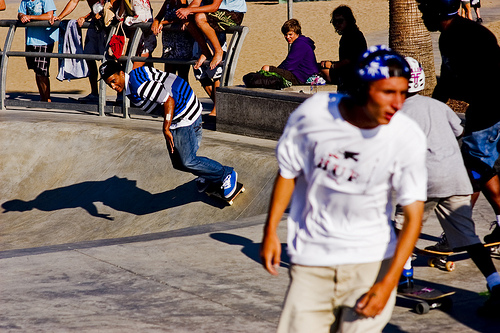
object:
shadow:
[1, 174, 237, 220]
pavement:
[0, 0, 499, 333]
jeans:
[167, 116, 233, 183]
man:
[97, 61, 237, 200]